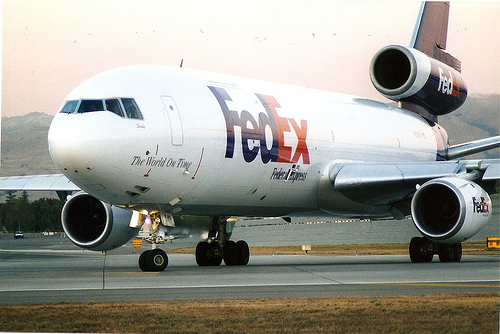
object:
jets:
[0, 0, 500, 266]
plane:
[46, 0, 498, 271]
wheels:
[222, 240, 251, 266]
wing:
[333, 159, 499, 189]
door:
[166, 101, 183, 146]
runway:
[0, 249, 499, 293]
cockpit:
[74, 100, 130, 117]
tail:
[398, 0, 460, 119]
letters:
[208, 85, 318, 166]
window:
[120, 99, 145, 121]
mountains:
[0, 108, 55, 171]